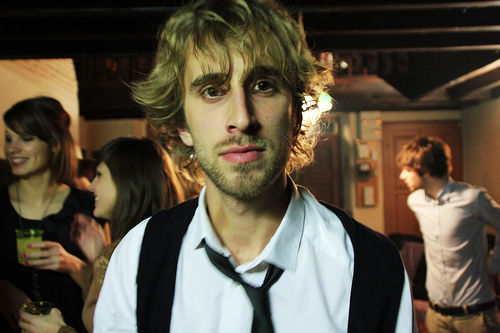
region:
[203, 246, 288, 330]
The tie the man is wearing.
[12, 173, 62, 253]
The necklace around the girl's neck.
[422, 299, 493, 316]
The belt the man is wearing.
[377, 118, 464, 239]
The wooden door on the right.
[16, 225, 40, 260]
The glass in the woman's hand with a yellow drink.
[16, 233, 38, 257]
The yellow liquid in the woman's cup.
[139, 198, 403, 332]
The black vest the man is wearing.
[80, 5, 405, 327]
The person is looking at the camera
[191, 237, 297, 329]
The person is wearing a tie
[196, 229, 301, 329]
The person's tie is black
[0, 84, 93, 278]
The woman has a drink in hand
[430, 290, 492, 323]
The person's belt is black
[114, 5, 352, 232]
The man has dirty blonde hair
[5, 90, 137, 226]
Two women in a conversation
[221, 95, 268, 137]
Nose of a man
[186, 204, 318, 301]
The man's collar is loose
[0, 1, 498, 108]
ceiling with exposed beams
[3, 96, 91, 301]
woman with drink in hand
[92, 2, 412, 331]
man with unkept hair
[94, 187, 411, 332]
vest over collared shirt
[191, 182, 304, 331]
loosened tie around neck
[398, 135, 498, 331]
thin man in buttoned down shirt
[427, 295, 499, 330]
belt in loops on pants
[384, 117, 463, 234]
brown wood door behind man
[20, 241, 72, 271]
hand with polished nails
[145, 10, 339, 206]
Young man with mouth closed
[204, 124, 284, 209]
Man with very light beard displayed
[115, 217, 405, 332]
Man wearing formal wear with black vest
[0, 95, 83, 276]
Young woman drinking a drink from green glass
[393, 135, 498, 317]
Young man with short brown hair looking around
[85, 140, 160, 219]
Young woman with short dark hair smiles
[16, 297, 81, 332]
Young woman holding her drink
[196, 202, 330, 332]
Young man with tie undone around neck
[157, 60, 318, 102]
Man with hair growing over eyes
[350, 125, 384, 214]
Utility meter on the side of a wall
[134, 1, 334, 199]
man with wavy hair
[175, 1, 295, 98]
bangs over man's eybrows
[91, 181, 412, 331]
vest on collared shirt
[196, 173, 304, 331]
loosened tie on neck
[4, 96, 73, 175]
face of smiling woman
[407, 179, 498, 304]
shirt buttoned down the front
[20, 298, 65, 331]
cup in woman's hand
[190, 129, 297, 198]
hair on man's face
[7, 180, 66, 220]
chain on woman's neck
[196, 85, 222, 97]
The left eye of the guy.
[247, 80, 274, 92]
The right eye of the guy.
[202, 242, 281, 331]
The tie the man is wearing.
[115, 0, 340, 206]
A guy has shaggy blonde hair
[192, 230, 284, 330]
A black knotted tie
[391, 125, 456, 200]
A guy has brown hair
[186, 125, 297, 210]
Facial hair on the guy's face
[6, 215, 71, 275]
A glass in a hand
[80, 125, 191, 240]
Woman has brown hair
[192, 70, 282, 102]
A pair of brown eyes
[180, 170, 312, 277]
White collar of a shirt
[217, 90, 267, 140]
Nose on a guy's face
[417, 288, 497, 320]
A black leather belt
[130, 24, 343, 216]
The man has a beard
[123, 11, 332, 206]
The man has blonde hair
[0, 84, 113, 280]
The girl is holding a drink